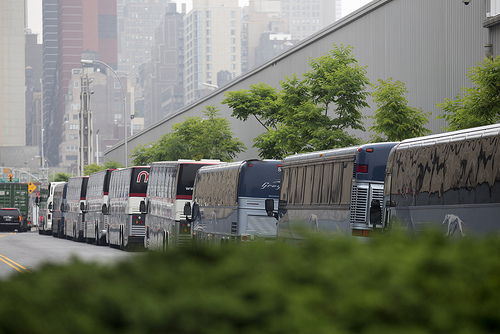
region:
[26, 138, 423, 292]
the buses are parked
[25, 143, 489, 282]
the buses are lined up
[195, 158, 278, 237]
it is a bus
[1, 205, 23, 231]
it is a black car in the road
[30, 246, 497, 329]
green bushes in the foreground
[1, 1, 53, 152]
a brown building in the background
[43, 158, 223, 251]
a row of buses parked in the street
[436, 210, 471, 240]
a greyhound bus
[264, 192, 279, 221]
side mirror on the bus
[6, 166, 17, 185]
a traffic light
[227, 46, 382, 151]
it is a green tree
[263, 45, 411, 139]
green trees beside the bus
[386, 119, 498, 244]
a large parked Greyhound bus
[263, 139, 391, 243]
a large parked Greyhound bus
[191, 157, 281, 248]
a large parked Greyhound bus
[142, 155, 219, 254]
a large parked Greyhound bus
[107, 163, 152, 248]
a large parked Greyhound bus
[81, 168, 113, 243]
a large parked Greyhound bus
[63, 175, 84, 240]
a large parked Greyhound bus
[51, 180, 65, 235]
a large parked Greyhound bus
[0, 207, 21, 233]
a black SUV in road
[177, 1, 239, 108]
large building in distance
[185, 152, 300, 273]
the bus is blue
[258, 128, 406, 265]
the bus is blue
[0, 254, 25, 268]
a yellow line on the ground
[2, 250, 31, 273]
a yellow line on the ground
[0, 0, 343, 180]
the tall buildings in the distance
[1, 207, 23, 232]
the car behind the large truck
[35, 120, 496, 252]
the line of buses next to the building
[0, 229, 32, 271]
the yellow lines on the ground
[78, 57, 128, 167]
the street light near the bus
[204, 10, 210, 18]
the window on the building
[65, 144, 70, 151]
the window on the building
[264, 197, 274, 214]
the mirror on the bus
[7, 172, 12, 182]
the traffic light in the distance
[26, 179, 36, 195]
the yellow street sign